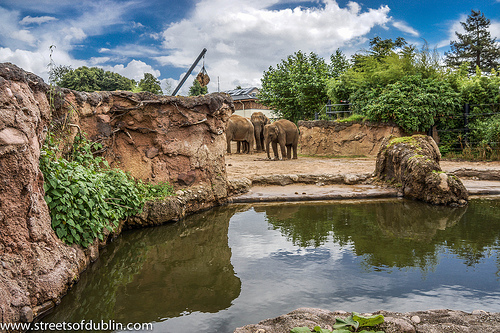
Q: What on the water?
A: Shadows.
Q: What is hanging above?
A: A crane with a rock.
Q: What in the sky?
A: Clouds.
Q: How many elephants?
A: 3.